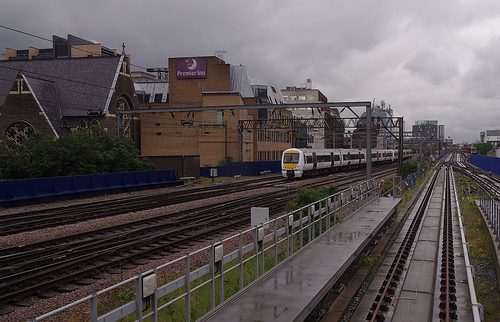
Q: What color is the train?
A: White.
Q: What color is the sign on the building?
A: Purple and white.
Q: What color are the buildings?
A: Brown.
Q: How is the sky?
A: Dark.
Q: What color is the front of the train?
A: Yellow.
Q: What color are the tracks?
A: Brown.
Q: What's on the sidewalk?
A: Rain puddles.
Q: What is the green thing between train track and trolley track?
A: Grass.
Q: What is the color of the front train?
A: Yellow.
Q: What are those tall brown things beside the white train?
A: Buildings.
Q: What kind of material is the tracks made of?
A: Metal.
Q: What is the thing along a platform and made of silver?
A: Railing.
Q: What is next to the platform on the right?
A: Track.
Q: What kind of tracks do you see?
A: Modern and traditional.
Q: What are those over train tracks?
A: Structures.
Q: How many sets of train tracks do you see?
A: 2.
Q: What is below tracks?
A: Concrete.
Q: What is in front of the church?
A: Trees.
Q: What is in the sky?
A: Clouds.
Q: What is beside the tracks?
A: Row of buildings.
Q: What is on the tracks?
A: Commuter train.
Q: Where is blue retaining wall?
A: Beside tracks.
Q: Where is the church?
A: Beside train track.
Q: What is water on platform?
A: Rain puddles.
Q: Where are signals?
A: Overhead on tracks.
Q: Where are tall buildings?
A: Beside tracks.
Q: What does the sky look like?
A: Overcast.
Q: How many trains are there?
A: 1.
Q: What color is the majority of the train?
A: White.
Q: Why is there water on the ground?
A: Because of rain.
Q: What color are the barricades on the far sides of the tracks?
A: Blue.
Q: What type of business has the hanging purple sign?
A: An inn.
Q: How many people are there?
A: None.